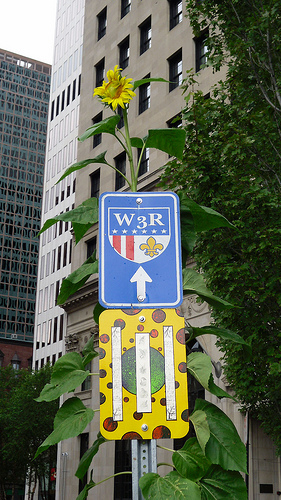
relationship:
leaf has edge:
[187, 396, 253, 476] [198, 399, 234, 424]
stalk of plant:
[122, 117, 143, 188] [39, 60, 250, 499]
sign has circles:
[97, 310, 191, 443] [149, 310, 166, 341]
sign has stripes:
[97, 310, 191, 443] [111, 327, 180, 422]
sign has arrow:
[94, 193, 189, 311] [130, 261, 154, 299]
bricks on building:
[3, 341, 35, 379] [0, 48, 51, 371]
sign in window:
[47, 464, 59, 485] [30, 421, 61, 498]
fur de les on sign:
[136, 235, 163, 258] [94, 193, 189, 311]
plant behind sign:
[39, 60, 250, 499] [94, 193, 189, 311]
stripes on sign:
[111, 327, 180, 422] [97, 310, 191, 443]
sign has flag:
[94, 193, 189, 311] [111, 222, 138, 264]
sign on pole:
[94, 193, 189, 311] [129, 441, 166, 499]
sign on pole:
[97, 310, 191, 443] [129, 441, 166, 499]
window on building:
[38, 182, 78, 208] [14, 0, 84, 499]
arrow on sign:
[130, 261, 154, 299] [94, 193, 189, 311]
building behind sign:
[57, 5, 280, 499] [94, 193, 189, 311]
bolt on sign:
[138, 197, 146, 202] [94, 193, 189, 311]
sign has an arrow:
[94, 193, 189, 311] [130, 261, 154, 299]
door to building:
[108, 440, 135, 498] [57, 5, 280, 499]